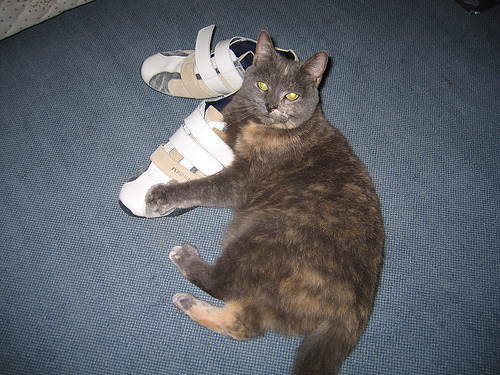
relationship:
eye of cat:
[285, 91, 299, 101] [212, 26, 350, 171]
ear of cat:
[241, 22, 282, 65] [198, 20, 374, 232]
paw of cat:
[136, 168, 201, 228] [190, 37, 384, 224]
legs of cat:
[150, 228, 250, 357] [196, 19, 381, 189]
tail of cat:
[294, 324, 370, 373] [218, 28, 354, 180]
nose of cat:
[259, 97, 282, 118] [203, 33, 379, 240]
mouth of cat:
[267, 116, 294, 128] [145, 30, 387, 375]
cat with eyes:
[161, 24, 393, 344] [245, 73, 312, 103]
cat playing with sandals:
[145, 30, 387, 375] [121, 31, 286, 223]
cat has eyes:
[145, 30, 387, 375] [252, 68, 302, 104]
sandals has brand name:
[88, 95, 266, 255] [161, 162, 204, 202]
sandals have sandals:
[87, 33, 327, 276] [140, 23, 295, 99]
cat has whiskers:
[145, 30, 387, 375] [216, 93, 336, 145]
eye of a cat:
[278, 86, 305, 113] [174, 20, 383, 372]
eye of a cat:
[243, 68, 279, 106] [161, 24, 401, 371]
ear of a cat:
[292, 44, 332, 91] [156, 31, 386, 360]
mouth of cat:
[262, 113, 305, 130] [178, 62, 362, 371]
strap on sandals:
[211, 35, 246, 94] [118, 81, 326, 219]